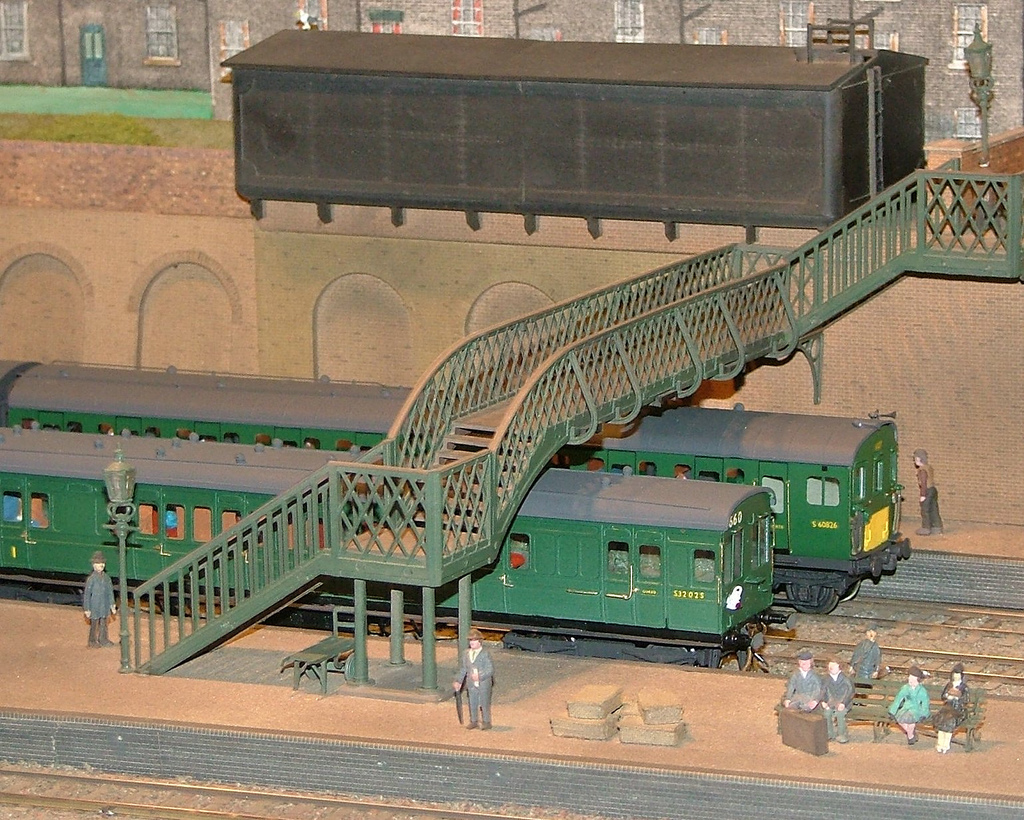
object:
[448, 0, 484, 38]
window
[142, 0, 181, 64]
window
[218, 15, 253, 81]
window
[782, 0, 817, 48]
window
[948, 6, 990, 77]
window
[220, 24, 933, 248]
structure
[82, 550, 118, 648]
man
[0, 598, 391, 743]
platform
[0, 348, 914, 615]
train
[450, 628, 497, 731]
man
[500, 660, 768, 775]
platform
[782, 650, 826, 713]
man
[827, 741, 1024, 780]
platform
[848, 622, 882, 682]
man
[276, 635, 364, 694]
bench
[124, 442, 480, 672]
stairs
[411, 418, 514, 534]
stairs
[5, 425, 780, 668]
train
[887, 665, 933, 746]
passenger